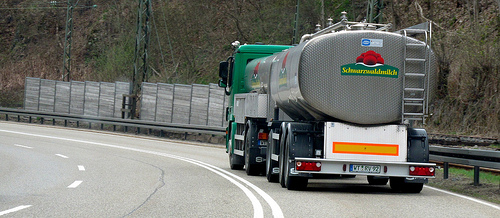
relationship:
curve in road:
[10, 106, 490, 214] [29, 119, 489, 216]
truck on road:
[221, 22, 444, 200] [3, 105, 496, 214]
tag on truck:
[348, 47, 407, 77] [223, 16, 441, 186]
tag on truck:
[323, 121, 406, 162] [221, 22, 444, 200]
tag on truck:
[323, 121, 406, 162] [223, 16, 441, 186]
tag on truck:
[323, 121, 406, 162] [221, 26, 430, 192]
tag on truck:
[323, 123, 405, 163] [216, 13, 434, 195]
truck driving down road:
[221, 22, 444, 200] [29, 119, 489, 216]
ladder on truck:
[397, 23, 429, 124] [223, 16, 441, 186]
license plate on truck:
[349, 164, 382, 174] [223, 16, 441, 186]